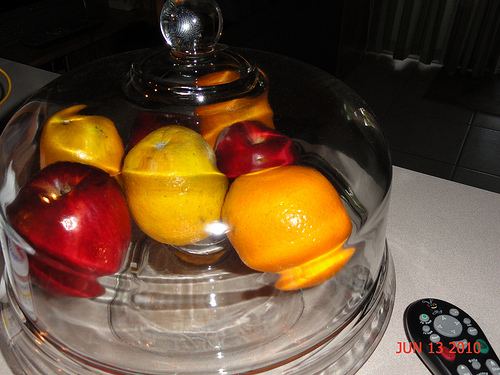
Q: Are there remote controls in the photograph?
A: Yes, there is a remote control.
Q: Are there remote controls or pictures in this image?
A: Yes, there is a remote control.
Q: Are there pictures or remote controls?
A: Yes, there is a remote control.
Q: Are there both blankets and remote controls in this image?
A: No, there is a remote control but no blankets.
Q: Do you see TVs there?
A: No, there are no tvs.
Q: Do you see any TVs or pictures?
A: No, there are no TVs or pictures.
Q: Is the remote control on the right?
A: Yes, the remote control is on the right of the image.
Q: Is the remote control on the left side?
A: No, the remote control is on the right of the image.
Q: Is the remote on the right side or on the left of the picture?
A: The remote is on the right of the image.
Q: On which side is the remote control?
A: The remote control is on the right of the image.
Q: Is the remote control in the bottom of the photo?
A: Yes, the remote control is in the bottom of the image.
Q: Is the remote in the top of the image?
A: No, the remote is in the bottom of the image.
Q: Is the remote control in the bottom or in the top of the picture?
A: The remote control is in the bottom of the image.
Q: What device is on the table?
A: The device is a remote control.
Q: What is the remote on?
A: The remote is on the table.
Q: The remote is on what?
A: The remote is on the table.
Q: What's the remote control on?
A: The remote is on the table.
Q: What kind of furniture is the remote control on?
A: The remote control is on the table.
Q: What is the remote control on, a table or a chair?
A: The remote control is on a table.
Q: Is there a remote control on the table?
A: Yes, there is a remote control on the table.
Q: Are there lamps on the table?
A: No, there is a remote control on the table.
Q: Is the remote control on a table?
A: Yes, the remote control is on a table.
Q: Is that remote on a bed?
A: No, the remote is on a table.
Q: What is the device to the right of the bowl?
A: The device is a remote control.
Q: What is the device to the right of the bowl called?
A: The device is a remote control.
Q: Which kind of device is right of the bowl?
A: The device is a remote control.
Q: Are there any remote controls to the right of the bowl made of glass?
A: Yes, there is a remote control to the right of the bowl.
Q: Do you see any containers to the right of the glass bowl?
A: No, there is a remote control to the right of the bowl.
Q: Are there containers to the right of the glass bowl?
A: No, there is a remote control to the right of the bowl.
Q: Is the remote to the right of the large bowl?
A: Yes, the remote is to the right of the bowl.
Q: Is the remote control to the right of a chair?
A: No, the remote control is to the right of the bowl.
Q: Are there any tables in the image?
A: Yes, there is a table.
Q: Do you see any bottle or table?
A: Yes, there is a table.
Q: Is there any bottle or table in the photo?
A: Yes, there is a table.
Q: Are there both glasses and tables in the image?
A: No, there is a table but no glasses.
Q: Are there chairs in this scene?
A: No, there are no chairs.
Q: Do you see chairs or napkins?
A: No, there are no chairs or napkins.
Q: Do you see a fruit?
A: Yes, there is a fruit.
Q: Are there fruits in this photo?
A: Yes, there is a fruit.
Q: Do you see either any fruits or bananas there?
A: Yes, there is a fruit.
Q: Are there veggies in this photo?
A: No, there are no veggies.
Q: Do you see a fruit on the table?
A: Yes, there is a fruit on the table.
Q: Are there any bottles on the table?
A: No, there is a fruit on the table.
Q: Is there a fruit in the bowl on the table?
A: Yes, there is a fruit in the bowl.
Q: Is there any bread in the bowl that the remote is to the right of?
A: No, there is a fruit in the bowl.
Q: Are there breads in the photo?
A: No, there are no breads.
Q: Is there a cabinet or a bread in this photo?
A: No, there are no breads or cabinets.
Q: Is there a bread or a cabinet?
A: No, there are no breads or cabinets.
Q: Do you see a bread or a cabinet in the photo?
A: No, there are no breads or cabinets.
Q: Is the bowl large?
A: Yes, the bowl is large.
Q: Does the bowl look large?
A: Yes, the bowl is large.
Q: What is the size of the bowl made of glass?
A: The bowl is large.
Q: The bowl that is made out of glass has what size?
A: The bowl is large.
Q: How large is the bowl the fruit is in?
A: The bowl is large.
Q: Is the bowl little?
A: No, the bowl is large.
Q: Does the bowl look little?
A: No, the bowl is large.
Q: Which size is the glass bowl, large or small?
A: The bowl is large.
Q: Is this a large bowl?
A: Yes, this is a large bowl.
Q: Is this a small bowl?
A: No, this is a large bowl.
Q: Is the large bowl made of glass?
A: Yes, the bowl is made of glass.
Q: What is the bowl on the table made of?
A: The bowl is made of glass.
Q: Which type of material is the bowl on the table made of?
A: The bowl is made of glass.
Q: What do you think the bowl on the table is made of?
A: The bowl is made of glass.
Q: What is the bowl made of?
A: The bowl is made of glass.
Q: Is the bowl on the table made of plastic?
A: No, the bowl is made of glass.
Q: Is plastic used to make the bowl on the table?
A: No, the bowl is made of glass.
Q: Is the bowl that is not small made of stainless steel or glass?
A: The bowl is made of glass.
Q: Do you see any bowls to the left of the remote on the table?
A: Yes, there is a bowl to the left of the remote.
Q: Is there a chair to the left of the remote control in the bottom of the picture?
A: No, there is a bowl to the left of the remote.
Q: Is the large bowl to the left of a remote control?
A: Yes, the bowl is to the left of a remote control.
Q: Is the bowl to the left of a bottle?
A: No, the bowl is to the left of a remote control.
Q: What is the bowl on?
A: The bowl is on the table.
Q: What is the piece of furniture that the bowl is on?
A: The piece of furniture is a table.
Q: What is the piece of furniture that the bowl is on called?
A: The piece of furniture is a table.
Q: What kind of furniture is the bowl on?
A: The bowl is on the table.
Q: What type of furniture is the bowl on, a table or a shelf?
A: The bowl is on a table.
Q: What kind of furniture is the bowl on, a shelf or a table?
A: The bowl is on a table.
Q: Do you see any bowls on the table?
A: Yes, there is a bowl on the table.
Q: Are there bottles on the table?
A: No, there is a bowl on the table.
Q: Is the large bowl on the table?
A: Yes, the bowl is on the table.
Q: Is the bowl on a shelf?
A: No, the bowl is on the table.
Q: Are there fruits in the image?
A: Yes, there is a fruit.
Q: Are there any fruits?
A: Yes, there is a fruit.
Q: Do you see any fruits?
A: Yes, there is a fruit.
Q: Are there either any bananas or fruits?
A: Yes, there is a fruit.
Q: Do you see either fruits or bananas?
A: Yes, there is a fruit.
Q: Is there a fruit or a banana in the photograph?
A: Yes, there is a fruit.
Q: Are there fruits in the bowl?
A: Yes, there is a fruit in the bowl.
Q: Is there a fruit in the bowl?
A: Yes, there is a fruit in the bowl.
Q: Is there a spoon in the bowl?
A: No, there is a fruit in the bowl.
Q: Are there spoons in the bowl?
A: No, there is a fruit in the bowl.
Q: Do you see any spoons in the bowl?
A: No, there is a fruit in the bowl.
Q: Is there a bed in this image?
A: No, there are no beds.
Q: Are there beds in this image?
A: No, there are no beds.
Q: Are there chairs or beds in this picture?
A: No, there are no beds or chairs.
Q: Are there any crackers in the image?
A: No, there are no crackers.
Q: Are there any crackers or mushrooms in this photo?
A: No, there are no crackers or mushrooms.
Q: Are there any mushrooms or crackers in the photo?
A: No, there are no crackers or mushrooms.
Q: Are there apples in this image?
A: Yes, there is an apple.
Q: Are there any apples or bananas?
A: Yes, there is an apple.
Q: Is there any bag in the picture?
A: No, there are no bags.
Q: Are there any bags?
A: No, there are no bags.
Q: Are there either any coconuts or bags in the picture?
A: No, there are no bags or coconuts.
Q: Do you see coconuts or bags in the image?
A: No, there are no bags or coconuts.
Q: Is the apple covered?
A: Yes, the apple is covered.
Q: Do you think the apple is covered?
A: Yes, the apple is covered.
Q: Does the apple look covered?
A: Yes, the apple is covered.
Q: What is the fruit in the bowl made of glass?
A: The fruit is an apple.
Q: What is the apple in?
A: The apple is in the bowl.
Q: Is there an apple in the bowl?
A: Yes, there is an apple in the bowl.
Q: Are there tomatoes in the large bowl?
A: No, there is an apple in the bowl.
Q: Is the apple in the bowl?
A: Yes, the apple is in the bowl.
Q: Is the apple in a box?
A: No, the apple is in the bowl.